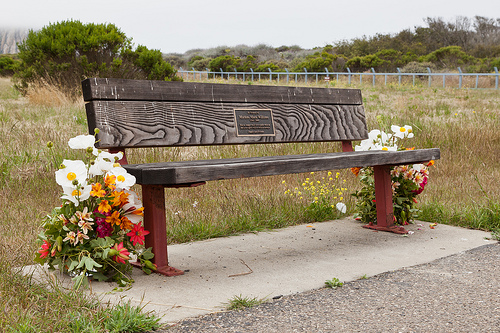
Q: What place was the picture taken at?
A: It was taken at the field.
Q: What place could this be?
A: It is a field.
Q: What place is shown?
A: It is a field.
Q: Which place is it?
A: It is a field.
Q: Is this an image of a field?
A: Yes, it is showing a field.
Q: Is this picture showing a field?
A: Yes, it is showing a field.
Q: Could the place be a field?
A: Yes, it is a field.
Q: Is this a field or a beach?
A: It is a field.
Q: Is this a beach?
A: No, it is a field.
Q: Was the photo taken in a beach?
A: No, the picture was taken in a field.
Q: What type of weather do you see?
A: It is overcast.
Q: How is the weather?
A: It is overcast.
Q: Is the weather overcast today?
A: Yes, it is overcast.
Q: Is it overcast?
A: Yes, it is overcast.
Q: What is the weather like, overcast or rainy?
A: It is overcast.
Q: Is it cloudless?
A: No, it is overcast.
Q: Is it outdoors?
A: Yes, it is outdoors.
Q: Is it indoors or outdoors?
A: It is outdoors.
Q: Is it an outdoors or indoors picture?
A: It is outdoors.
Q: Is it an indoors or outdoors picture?
A: It is outdoors.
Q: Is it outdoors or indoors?
A: It is outdoors.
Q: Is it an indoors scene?
A: No, it is outdoors.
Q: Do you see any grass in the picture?
A: Yes, there is grass.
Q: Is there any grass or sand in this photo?
A: Yes, there is grass.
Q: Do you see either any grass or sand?
A: Yes, there is grass.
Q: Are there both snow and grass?
A: No, there is grass but no snow.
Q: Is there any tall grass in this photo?
A: Yes, there is tall grass.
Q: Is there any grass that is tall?
A: Yes, there is grass that is tall.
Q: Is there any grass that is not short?
A: Yes, there is tall grass.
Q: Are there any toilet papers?
A: No, there are no toilet papers.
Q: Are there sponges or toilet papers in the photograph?
A: No, there are no toilet papers or sponges.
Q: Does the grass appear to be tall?
A: Yes, the grass is tall.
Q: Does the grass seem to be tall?
A: Yes, the grass is tall.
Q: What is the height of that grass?
A: The grass is tall.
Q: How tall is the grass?
A: The grass is tall.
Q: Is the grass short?
A: No, the grass is tall.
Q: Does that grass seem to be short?
A: No, the grass is tall.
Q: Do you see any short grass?
A: No, there is grass but it is tall.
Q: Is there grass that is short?
A: No, there is grass but it is tall.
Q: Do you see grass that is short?
A: No, there is grass but it is tall.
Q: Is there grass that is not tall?
A: No, there is grass but it is tall.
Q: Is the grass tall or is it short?
A: The grass is tall.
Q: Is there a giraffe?
A: No, there are no giraffes.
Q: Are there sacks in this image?
A: No, there are no sacks.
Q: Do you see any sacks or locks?
A: No, there are no sacks or locks.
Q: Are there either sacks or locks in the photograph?
A: No, there are no sacks or locks.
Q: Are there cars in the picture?
A: No, there are no cars.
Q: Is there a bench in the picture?
A: Yes, there is a bench.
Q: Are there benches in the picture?
A: Yes, there is a bench.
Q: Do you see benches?
A: Yes, there is a bench.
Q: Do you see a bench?
A: Yes, there is a bench.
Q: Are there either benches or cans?
A: Yes, there is a bench.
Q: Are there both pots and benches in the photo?
A: No, there is a bench but no pots.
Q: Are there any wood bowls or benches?
A: Yes, there is a wood bench.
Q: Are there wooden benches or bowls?
A: Yes, there is a wood bench.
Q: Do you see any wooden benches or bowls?
A: Yes, there is a wood bench.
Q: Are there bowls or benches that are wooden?
A: Yes, the bench is wooden.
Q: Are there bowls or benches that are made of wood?
A: Yes, the bench is made of wood.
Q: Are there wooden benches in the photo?
A: Yes, there is a wood bench.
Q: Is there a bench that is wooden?
A: Yes, there is a bench that is wooden.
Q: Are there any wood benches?
A: Yes, there is a bench that is made of wood.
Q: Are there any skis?
A: No, there are no skis.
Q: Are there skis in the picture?
A: No, there are no skis.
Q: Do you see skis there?
A: No, there are no skis.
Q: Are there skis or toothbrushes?
A: No, there are no skis or toothbrushes.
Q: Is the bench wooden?
A: Yes, the bench is wooden.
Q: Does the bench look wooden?
A: Yes, the bench is wooden.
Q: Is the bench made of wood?
A: Yes, the bench is made of wood.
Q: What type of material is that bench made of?
A: The bench is made of wood.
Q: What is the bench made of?
A: The bench is made of wood.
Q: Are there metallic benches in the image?
A: No, there is a bench but it is wooden.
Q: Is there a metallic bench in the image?
A: No, there is a bench but it is wooden.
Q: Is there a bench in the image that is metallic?
A: No, there is a bench but it is wooden.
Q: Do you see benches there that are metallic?
A: No, there is a bench but it is wooden.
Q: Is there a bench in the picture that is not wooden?
A: No, there is a bench but it is wooden.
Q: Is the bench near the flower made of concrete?
A: No, the bench is made of wood.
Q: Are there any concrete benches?
A: No, there is a bench but it is made of wood.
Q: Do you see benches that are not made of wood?
A: No, there is a bench but it is made of wood.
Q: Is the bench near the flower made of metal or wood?
A: The bench is made of wood.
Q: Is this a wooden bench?
A: Yes, this is a wooden bench.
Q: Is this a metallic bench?
A: No, this is a wooden bench.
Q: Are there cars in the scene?
A: No, there are no cars.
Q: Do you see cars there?
A: No, there are no cars.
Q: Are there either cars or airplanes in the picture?
A: No, there are no cars or airplanes.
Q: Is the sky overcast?
A: Yes, the sky is overcast.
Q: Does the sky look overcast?
A: Yes, the sky is overcast.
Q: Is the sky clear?
A: No, the sky is overcast.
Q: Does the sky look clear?
A: No, the sky is overcast.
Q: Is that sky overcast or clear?
A: The sky is overcast.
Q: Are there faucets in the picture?
A: No, there are no faucets.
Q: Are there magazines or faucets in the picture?
A: No, there are no faucets or magazines.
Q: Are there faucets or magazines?
A: No, there are no faucets or magazines.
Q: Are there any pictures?
A: No, there are no pictures.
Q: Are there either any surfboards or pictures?
A: No, there are no pictures or surfboards.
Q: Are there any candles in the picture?
A: No, there are no candles.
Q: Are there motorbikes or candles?
A: No, there are no candles or motorbikes.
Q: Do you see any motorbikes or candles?
A: No, there are no candles or motorbikes.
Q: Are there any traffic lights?
A: No, there are no traffic lights.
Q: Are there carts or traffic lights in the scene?
A: No, there are no traffic lights or carts.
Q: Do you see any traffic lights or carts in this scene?
A: No, there are no traffic lights or carts.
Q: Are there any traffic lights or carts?
A: No, there are no traffic lights or carts.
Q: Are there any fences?
A: Yes, there is a fence.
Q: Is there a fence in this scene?
A: Yes, there is a fence.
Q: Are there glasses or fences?
A: Yes, there is a fence.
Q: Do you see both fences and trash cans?
A: No, there is a fence but no trash cans.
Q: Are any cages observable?
A: No, there are no cages.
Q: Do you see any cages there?
A: No, there are no cages.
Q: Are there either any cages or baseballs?
A: No, there are no cages or baseballs.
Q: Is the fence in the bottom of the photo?
A: No, the fence is in the top of the image.